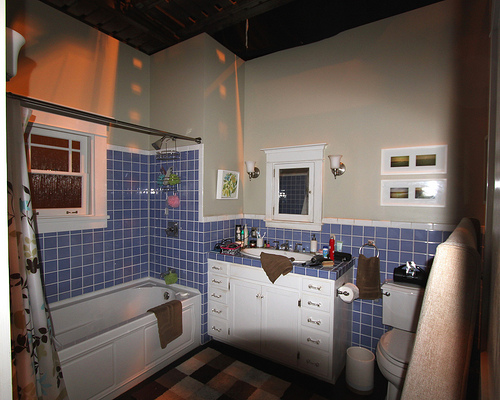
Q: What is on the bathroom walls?
A: Orange light.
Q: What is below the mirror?
A: Sink and countertop.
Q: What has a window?
A: Bathtub and shower.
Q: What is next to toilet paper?
A: White toilet.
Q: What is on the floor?
A: Rug.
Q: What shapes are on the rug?
A: Squares.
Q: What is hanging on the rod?
A: Shower curtain.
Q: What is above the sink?
A: Medicine cabinet.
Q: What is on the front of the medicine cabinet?
A: Mirror.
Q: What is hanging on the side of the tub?
A: Towel.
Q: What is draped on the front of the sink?
A: Towel.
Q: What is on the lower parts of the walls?
A: Tile.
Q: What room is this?
A: Bathroom.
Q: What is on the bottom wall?
A: Tiles.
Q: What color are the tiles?
A: Blue.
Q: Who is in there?
A: No people.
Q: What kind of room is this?
A: Bathroom.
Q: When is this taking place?
A: Night time.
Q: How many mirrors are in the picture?
A: One.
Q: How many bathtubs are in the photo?
A: One.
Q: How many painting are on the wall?
A: Five.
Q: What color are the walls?
A: Tan.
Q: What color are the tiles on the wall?
A: Blue.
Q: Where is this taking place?
A: In a house.